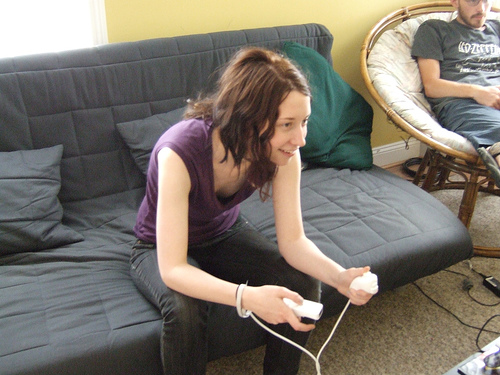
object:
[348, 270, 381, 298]
controller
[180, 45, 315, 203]
hair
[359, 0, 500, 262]
chair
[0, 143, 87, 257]
pillow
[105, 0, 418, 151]
wall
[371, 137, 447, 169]
trim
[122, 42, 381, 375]
girl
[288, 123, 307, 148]
nose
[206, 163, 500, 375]
carpet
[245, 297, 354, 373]
cord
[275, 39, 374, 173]
pillows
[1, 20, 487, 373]
couch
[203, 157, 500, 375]
floor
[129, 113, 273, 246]
shirt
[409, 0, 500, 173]
boy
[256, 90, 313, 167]
face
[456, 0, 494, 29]
face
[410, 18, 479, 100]
arm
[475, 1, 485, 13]
nose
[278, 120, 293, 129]
eye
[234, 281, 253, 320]
bracelet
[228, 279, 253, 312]
wrist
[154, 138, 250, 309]
arm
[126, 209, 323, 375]
jeans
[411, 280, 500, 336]
cables